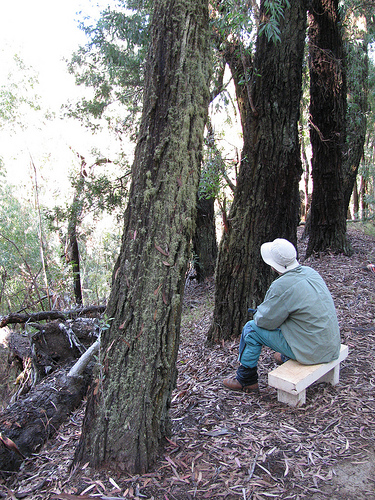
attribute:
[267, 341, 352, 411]
bench — white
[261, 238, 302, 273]
hat — white